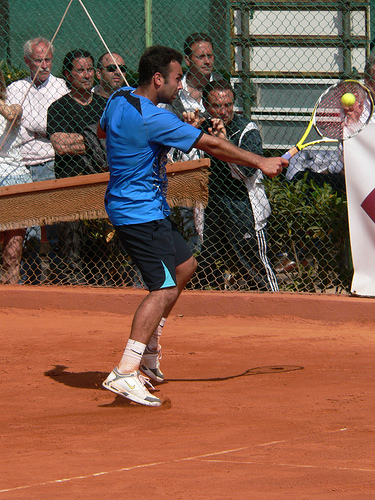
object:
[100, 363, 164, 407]
foot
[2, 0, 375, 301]
fence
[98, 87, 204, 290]
tennis clothes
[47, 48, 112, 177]
spectator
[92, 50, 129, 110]
spectator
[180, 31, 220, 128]
spectator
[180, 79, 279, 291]
spectator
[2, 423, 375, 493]
white line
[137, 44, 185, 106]
man's head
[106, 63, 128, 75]
sunglasses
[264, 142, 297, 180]
handle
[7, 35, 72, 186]
man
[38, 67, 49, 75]
mustache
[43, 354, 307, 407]
shadow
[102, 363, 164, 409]
shoes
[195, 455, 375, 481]
line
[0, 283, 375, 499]
court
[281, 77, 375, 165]
racket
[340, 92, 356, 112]
ball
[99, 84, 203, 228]
blue shirt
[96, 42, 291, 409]
man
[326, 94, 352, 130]
strings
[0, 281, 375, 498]
clay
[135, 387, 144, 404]
white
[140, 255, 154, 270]
black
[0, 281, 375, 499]
ground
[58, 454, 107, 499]
dirt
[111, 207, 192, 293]
shorts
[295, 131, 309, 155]
yellow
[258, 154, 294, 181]
hand